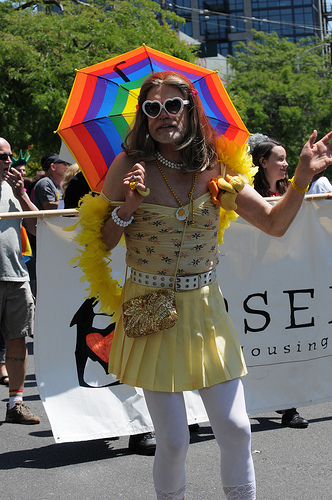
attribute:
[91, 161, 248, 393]
dress — yellow, pleated, short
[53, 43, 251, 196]
umbrella — colorful, small, rainbow striped, rainbow colored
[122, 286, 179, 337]
purse — sequined, gold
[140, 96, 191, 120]
sunglasses — white, heart-shaped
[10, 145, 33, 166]
hat — statue of liberty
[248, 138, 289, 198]
person — smiling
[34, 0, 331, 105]
building — windowed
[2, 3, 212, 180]
trees — green, tall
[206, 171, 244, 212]
stuffed animal — small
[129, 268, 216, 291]
belt — white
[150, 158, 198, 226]
necklace — beaded, yellow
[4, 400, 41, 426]
tennis shoe — tied, brown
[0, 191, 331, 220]
pole — brown, long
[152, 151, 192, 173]
bracelet — white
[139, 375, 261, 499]
leggings — white, lace, stretchy, laced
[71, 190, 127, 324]
boa — yellow, feather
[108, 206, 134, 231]
bracelet — white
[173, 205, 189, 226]
daisy pin — white, yellow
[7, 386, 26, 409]
sock — rainbow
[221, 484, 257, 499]
cuff — lace, white